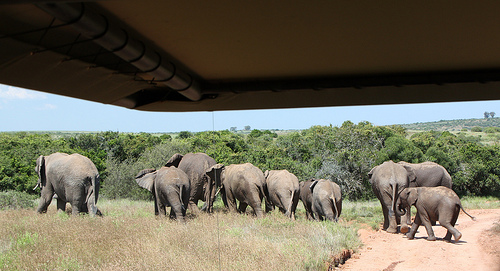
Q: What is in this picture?
A: Herd of elephants.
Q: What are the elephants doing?
A: Grazing.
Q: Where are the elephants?
A: Africa.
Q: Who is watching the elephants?
A: Photographer.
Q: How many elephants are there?
A: 8.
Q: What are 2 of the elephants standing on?
A: A road.